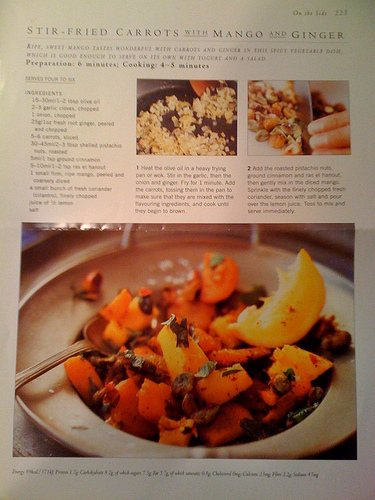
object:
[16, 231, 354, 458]
plate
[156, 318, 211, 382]
food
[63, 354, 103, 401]
food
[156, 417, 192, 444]
food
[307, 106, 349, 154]
hand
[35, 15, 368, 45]
title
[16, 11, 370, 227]
article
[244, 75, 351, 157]
image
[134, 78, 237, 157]
image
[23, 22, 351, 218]
instructions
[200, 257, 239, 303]
carrot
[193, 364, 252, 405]
carrot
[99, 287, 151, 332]
carrot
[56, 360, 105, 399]
carrot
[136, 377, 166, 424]
carrot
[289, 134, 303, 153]
ground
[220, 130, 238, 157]
ground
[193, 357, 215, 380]
herb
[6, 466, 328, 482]
caption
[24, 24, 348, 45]
dish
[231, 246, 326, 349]
lemon wedge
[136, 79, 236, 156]
chopped ginger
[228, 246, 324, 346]
slice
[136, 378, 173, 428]
food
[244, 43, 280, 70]
ground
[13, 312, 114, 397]
spoon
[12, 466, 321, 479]
information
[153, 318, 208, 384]
peice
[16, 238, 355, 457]
bowl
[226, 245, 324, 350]
wedge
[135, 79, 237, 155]
bread crumbs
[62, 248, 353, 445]
ingredients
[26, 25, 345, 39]
name